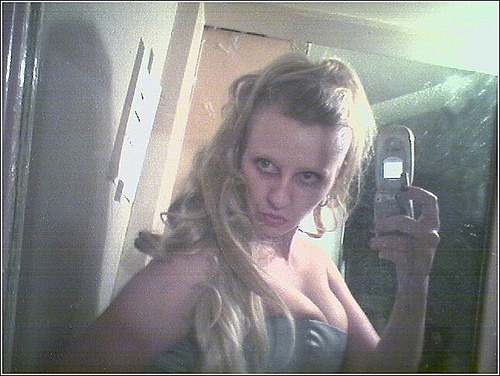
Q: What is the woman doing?
A: Taking a photo.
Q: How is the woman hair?
A: In Curls.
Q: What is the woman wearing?
A: Low cut dress.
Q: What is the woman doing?
A: Posing for a picture.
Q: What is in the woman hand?
A: A cellphone.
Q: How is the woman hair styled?
A: Long blond hair.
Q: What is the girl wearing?
A: A gray top.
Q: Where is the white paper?
A: On the wall.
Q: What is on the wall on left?
A: Shadow of the girl.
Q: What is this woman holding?
A: A cellphone.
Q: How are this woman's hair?
A: Long and blonde.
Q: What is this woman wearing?
A: Green strapless top.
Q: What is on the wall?
A: Calendar.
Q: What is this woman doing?
A: Taking a selfie.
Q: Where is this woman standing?
A: In front of a mirror.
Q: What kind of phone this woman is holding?
A: Flip phone.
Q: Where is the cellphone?
A: In the woman's hand.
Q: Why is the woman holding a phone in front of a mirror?
A: She is taking a picture of herself.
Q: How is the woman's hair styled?
A: In a ponytail.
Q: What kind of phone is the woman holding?
A: A gray cellphone.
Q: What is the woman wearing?
A: A green halter top.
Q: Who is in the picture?
A: A woman.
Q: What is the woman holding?
A: A phone.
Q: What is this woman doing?
A: Taking a selfie.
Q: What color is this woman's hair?
A: Blonde.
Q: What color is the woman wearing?
A: Blue.